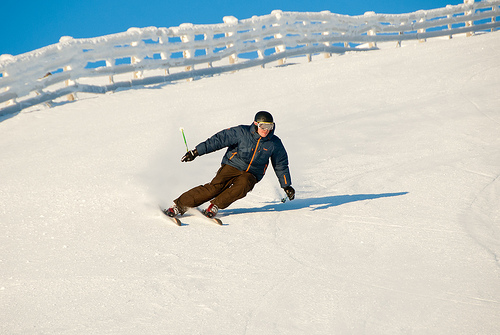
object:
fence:
[3, 4, 498, 120]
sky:
[4, 2, 490, 41]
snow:
[0, 29, 499, 335]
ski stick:
[179, 127, 190, 152]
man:
[158, 107, 296, 226]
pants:
[172, 165, 260, 210]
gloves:
[180, 148, 202, 163]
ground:
[2, 39, 494, 334]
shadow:
[212, 191, 410, 218]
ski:
[157, 204, 184, 228]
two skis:
[157, 202, 229, 226]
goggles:
[256, 120, 274, 132]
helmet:
[253, 111, 278, 124]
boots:
[163, 202, 221, 218]